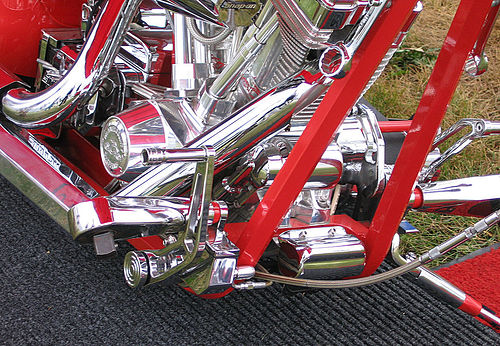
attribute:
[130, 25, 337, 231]
tube — shiny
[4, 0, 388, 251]
motor — shiny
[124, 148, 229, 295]
pedal — silver, chrome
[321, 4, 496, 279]
bar — red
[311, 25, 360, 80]
wrench — chrome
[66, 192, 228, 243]
foot pedal — chrome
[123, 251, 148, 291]
metal screw — round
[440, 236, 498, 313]
carpeting — red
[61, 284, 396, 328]
carpet — dark black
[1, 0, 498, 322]
motorcycle — red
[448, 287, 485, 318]
tape — red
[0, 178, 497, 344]
mat — black, gray, ridged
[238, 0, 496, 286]
frame — red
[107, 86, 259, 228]
engine — chrome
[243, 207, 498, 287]
tube — gray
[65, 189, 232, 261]
ratchet — chrome-plated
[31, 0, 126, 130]
exhaust tube — chrome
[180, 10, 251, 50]
metal hose — flexible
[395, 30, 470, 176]
grass — green, brown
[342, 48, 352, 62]
silver — metal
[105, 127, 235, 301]
foot rest — chrome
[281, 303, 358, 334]
mat — black, grooved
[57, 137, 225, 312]
foot rest — chrome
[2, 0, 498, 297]
paint — red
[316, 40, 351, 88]
wrench head — silver